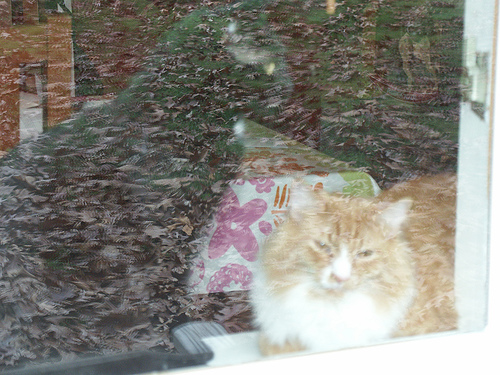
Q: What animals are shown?
A: Cats.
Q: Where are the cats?
A: Behind the window.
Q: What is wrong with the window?
A: It's dirty.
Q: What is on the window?
A: Dirt.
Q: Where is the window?
A: In front of the cats.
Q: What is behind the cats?
A: A table.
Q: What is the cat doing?
A: Laying down.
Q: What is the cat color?
A: Gold and white.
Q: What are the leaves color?
A: Green.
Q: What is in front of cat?
A: Window.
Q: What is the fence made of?
A: Wood.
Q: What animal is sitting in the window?
A: Cat.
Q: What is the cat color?
A: Brown and white.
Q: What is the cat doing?
A: Looking out the window.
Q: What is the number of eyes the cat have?
A: Two.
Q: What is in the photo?
A: Cat.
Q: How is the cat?
A: Sad.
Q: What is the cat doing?
A: Relaxing.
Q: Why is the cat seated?
A: Relaxing.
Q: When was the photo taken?
A: Daytime.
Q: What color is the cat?
A: Brown and white.